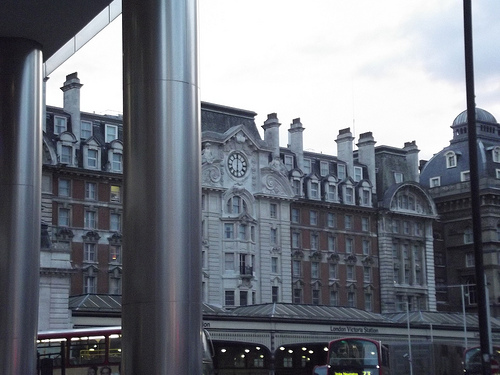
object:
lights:
[299, 346, 311, 352]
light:
[37, 337, 65, 342]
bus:
[39, 327, 128, 374]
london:
[329, 326, 346, 332]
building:
[41, 72, 498, 342]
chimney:
[259, 109, 283, 148]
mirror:
[65, 329, 139, 359]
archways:
[382, 180, 440, 314]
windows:
[291, 257, 306, 278]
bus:
[314, 334, 391, 374]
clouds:
[267, 8, 404, 105]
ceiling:
[278, 340, 317, 364]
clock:
[225, 148, 250, 179]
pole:
[462, 19, 483, 199]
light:
[452, 55, 484, 259]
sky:
[294, 28, 468, 63]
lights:
[401, 350, 411, 360]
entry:
[361, 329, 432, 374]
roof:
[278, 145, 339, 159]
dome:
[449, 103, 499, 140]